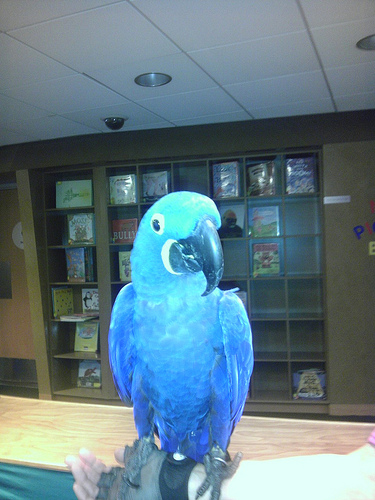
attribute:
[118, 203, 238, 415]
parrot — blue, large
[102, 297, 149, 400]
wing — blue, feathery, white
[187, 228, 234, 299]
beak — black, curled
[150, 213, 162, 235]
eye — black, white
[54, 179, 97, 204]
book — displayed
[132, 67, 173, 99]
light — round, inset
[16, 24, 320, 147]
tile — white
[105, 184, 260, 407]
bird — perched, large, blue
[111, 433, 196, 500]
glove — grey, gray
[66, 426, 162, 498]
hand — gloved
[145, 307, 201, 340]
chest — blue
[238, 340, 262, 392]
feathers — blue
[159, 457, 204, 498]
wrist band — black, snapped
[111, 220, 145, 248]
book — red, bully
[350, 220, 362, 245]
p — blue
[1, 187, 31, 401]
door — brown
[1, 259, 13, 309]
handle — metal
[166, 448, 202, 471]
buckle — silver